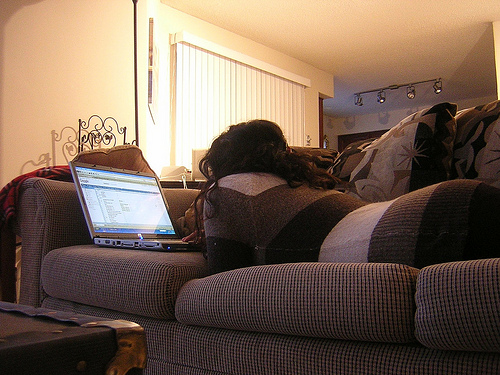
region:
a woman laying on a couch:
[151, 111, 478, 305]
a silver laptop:
[68, 137, 230, 277]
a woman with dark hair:
[173, 95, 327, 232]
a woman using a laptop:
[63, 70, 350, 260]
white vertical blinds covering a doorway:
[164, 67, 328, 164]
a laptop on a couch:
[49, 130, 216, 295]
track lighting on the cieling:
[338, 67, 450, 115]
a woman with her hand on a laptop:
[120, 114, 326, 280]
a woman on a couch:
[184, 100, 484, 320]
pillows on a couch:
[288, 96, 495, 218]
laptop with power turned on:
[67, 154, 194, 254]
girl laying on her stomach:
[171, 111, 498, 266]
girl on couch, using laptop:
[69, 111, 497, 283]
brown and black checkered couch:
[21, 128, 496, 373]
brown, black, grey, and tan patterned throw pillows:
[321, 94, 498, 202]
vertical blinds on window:
[160, 27, 312, 168]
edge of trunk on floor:
[0, 284, 157, 373]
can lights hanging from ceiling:
[350, 70, 447, 110]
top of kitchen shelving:
[74, 105, 129, 159]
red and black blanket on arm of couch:
[1, 154, 76, 273]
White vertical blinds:
[161, 22, 314, 120]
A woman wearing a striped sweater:
[168, 110, 445, 263]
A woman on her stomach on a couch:
[181, 116, 481, 365]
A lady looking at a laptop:
[66, 117, 328, 286]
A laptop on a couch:
[45, 155, 175, 292]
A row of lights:
[348, 70, 453, 110]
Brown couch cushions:
[162, 257, 488, 361]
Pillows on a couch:
[327, 98, 495, 174]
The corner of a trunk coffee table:
[8, 295, 164, 371]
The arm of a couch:
[14, 175, 79, 297]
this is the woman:
[190, 122, 333, 258]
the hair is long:
[271, 145, 304, 174]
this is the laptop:
[91, 180, 157, 226]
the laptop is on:
[103, 184, 155, 226]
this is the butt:
[393, 170, 490, 246]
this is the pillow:
[378, 100, 479, 175]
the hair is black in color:
[241, 124, 279, 163]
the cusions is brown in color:
[287, 266, 382, 336]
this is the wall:
[143, 17, 195, 97]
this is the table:
[75, 313, 138, 372]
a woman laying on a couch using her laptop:
[58, 120, 485, 309]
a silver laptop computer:
[68, 156, 188, 252]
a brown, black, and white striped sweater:
[212, 178, 458, 263]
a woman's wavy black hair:
[201, 125, 323, 187]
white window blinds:
[172, 32, 309, 152]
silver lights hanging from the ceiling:
[343, 80, 448, 107]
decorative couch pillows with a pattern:
[338, 125, 446, 193]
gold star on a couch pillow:
[393, 142, 426, 165]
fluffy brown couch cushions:
[45, 243, 411, 328]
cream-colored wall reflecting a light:
[7, 11, 124, 112]